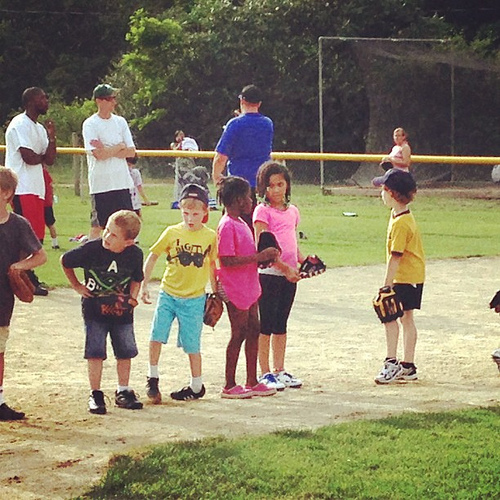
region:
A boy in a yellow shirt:
[360, 163, 429, 394]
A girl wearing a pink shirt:
[245, 157, 315, 391]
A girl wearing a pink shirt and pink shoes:
[208, 175, 283, 405]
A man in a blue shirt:
[206, 80, 277, 213]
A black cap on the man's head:
[233, 83, 265, 103]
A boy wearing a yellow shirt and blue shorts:
[139, 180, 227, 401]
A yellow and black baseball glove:
[368, 278, 410, 323]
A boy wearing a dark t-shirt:
[60, 208, 159, 410]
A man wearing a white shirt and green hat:
[75, 80, 149, 237]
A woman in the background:
[378, 125, 417, 199]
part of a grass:
[336, 402, 380, 464]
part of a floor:
[323, 383, 350, 416]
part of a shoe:
[374, 368, 396, 398]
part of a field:
[396, 433, 431, 487]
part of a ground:
[316, 386, 336, 420]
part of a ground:
[392, 410, 401, 420]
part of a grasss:
[362, 431, 393, 473]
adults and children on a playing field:
[15, 13, 491, 485]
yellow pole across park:
[5, 140, 496, 165]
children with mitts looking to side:
[0, 166, 220, 421]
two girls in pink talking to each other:
[215, 156, 305, 401]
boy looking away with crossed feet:
[366, 160, 431, 385]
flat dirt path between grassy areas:
[2, 182, 487, 492]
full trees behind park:
[2, 1, 492, 191]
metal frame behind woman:
[315, 31, 465, 192]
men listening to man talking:
[2, 80, 272, 185]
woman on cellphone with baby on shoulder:
[168, 126, 198, 171]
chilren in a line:
[55, 153, 440, 384]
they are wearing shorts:
[62, 156, 446, 412]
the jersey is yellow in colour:
[370, 208, 434, 285]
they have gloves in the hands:
[62, 249, 432, 329]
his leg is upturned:
[146, 345, 226, 405]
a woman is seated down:
[345, 119, 437, 230]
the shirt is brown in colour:
[211, 123, 269, 155]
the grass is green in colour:
[109, 418, 494, 495]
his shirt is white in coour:
[63, 106, 146, 196]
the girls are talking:
[216, 149, 316, 344]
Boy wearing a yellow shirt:
[150, 176, 221, 304]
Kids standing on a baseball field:
[0, 156, 428, 424]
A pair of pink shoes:
[218, 376, 278, 404]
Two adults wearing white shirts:
[2, 109, 141, 201]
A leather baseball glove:
[370, 282, 406, 325]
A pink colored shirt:
[252, 200, 304, 273]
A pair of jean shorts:
[80, 314, 140, 363]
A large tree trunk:
[344, 111, 439, 186]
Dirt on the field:
[1, 255, 498, 498]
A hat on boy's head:
[368, 163, 420, 210]